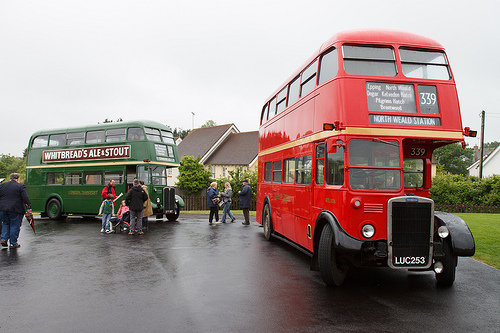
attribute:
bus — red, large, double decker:
[255, 34, 477, 289]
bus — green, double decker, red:
[26, 123, 178, 222]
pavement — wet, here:
[5, 212, 498, 333]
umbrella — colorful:
[22, 207, 35, 229]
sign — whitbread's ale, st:
[44, 146, 128, 157]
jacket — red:
[102, 187, 117, 202]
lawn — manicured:
[447, 211, 499, 263]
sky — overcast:
[0, 1, 497, 150]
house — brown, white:
[171, 124, 258, 188]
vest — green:
[102, 200, 112, 213]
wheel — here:
[317, 220, 342, 285]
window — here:
[343, 42, 398, 79]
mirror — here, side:
[325, 139, 336, 152]